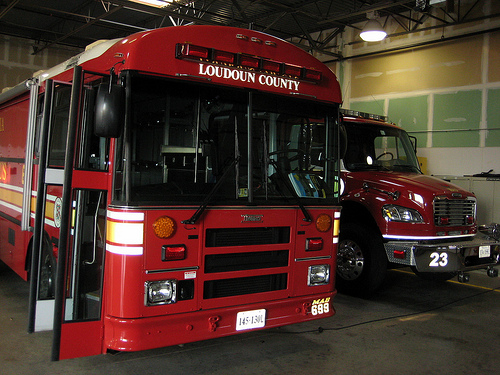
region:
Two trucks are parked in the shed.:
[22, 61, 479, 321]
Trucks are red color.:
[27, 145, 483, 315]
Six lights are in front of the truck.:
[142, 215, 332, 310]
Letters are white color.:
[197, 60, 308, 96]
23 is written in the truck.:
[420, 243, 460, 270]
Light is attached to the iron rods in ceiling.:
[337, 10, 402, 53]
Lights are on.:
[352, 5, 390, 51]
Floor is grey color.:
[348, 321, 453, 359]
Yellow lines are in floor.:
[455, 273, 496, 305]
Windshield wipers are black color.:
[178, 151, 324, 228]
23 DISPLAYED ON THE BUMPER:
[409, 242, 464, 282]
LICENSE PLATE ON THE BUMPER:
[469, 239, 494, 262]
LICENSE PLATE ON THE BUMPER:
[231, 306, 269, 336]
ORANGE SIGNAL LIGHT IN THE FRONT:
[150, 216, 180, 241]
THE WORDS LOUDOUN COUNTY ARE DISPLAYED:
[184, 56, 305, 100]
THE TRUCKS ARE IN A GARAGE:
[36, 20, 453, 367]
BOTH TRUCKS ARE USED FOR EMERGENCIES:
[58, 24, 473, 351]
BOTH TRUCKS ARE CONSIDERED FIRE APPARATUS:
[43, 36, 486, 343]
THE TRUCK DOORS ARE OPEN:
[23, 57, 142, 373]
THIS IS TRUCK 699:
[298, 292, 347, 336]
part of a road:
[416, 323, 465, 360]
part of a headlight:
[149, 282, 185, 303]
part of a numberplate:
[231, 305, 263, 341]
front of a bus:
[206, 201, 283, 281]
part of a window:
[205, 115, 285, 165]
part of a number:
[419, 242, 450, 274]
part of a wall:
[413, 81, 448, 111]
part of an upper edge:
[302, 55, 337, 85]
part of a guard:
[361, 200, 384, 219]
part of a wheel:
[345, 237, 376, 277]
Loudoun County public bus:
[28, 22, 370, 369]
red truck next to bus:
[134, 14, 498, 364]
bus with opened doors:
[27, 31, 351, 353]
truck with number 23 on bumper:
[299, 110, 499, 320]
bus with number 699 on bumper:
[79, 45, 362, 374]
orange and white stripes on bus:
[6, 95, 240, 336]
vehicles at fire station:
[27, 38, 493, 362]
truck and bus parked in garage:
[12, 5, 497, 367]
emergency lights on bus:
[159, 17, 361, 133]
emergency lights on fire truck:
[331, 77, 433, 169]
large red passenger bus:
[22, 17, 366, 357]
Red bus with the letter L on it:
[32, 38, 361, 345]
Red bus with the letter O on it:
[33, 18, 355, 346]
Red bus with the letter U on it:
[44, 17, 366, 368]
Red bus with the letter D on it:
[13, 30, 351, 367]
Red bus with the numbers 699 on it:
[5, 30, 335, 360]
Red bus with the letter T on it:
[10, 40, 365, 370]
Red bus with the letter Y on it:
[16, 14, 380, 351]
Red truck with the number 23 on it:
[353, 120, 490, 312]